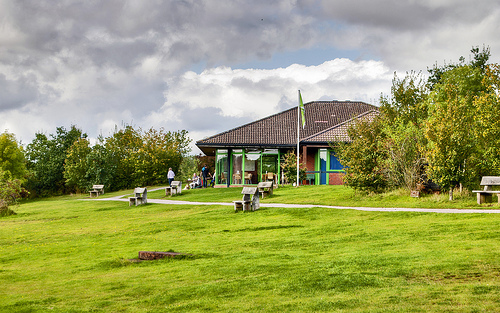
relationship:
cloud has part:
[1, 0, 498, 158] [168, 25, 247, 63]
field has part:
[1, 183, 498, 310] [227, 236, 272, 261]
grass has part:
[1, 183, 498, 310] [227, 236, 272, 261]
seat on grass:
[129, 188, 148, 208] [1, 183, 498, 310]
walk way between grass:
[82, 194, 498, 214] [1, 183, 498, 310]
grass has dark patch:
[1, 183, 498, 310] [230, 225, 300, 231]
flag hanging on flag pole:
[300, 96, 306, 130] [298, 90, 301, 188]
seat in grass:
[129, 188, 148, 208] [1, 183, 498, 310]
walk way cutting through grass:
[82, 194, 498, 214] [1, 183, 498, 310]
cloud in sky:
[1, 0, 498, 158] [1, 3, 498, 154]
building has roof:
[196, 100, 397, 191] [196, 100, 385, 156]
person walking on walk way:
[166, 167, 175, 187] [82, 194, 498, 214]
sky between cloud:
[1, 3, 498, 154] [1, 0, 498, 158]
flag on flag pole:
[300, 96, 306, 130] [298, 90, 301, 188]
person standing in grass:
[166, 167, 175, 187] [1, 183, 498, 310]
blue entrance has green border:
[316, 151, 329, 185] [314, 151, 330, 186]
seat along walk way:
[129, 188, 148, 208] [82, 194, 498, 214]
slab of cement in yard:
[140, 252, 187, 258] [1, 180, 498, 313]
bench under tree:
[472, 175, 498, 204] [468, 65, 498, 185]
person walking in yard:
[166, 167, 175, 187] [1, 180, 498, 313]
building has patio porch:
[196, 100, 397, 191] [217, 151, 282, 186]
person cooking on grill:
[201, 166, 213, 189] [211, 174, 215, 188]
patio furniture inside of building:
[244, 174, 253, 186] [196, 100, 397, 191]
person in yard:
[196, 177, 202, 189] [1, 180, 498, 313]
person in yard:
[166, 167, 175, 187] [1, 180, 498, 313]